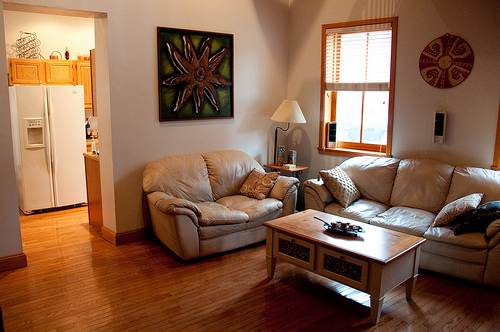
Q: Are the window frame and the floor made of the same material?
A: Yes, both the window frame and the floor are made of wood.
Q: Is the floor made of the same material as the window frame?
A: Yes, both the floor and the window frame are made of wood.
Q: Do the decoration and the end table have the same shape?
A: No, the decoration is round and the end table is square.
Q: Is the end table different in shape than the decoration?
A: Yes, the decoration is round and the end table is square.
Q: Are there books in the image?
A: No, there are no books.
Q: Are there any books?
A: No, there are no books.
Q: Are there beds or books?
A: No, there are no books or beds.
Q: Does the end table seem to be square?
A: Yes, the end table is square.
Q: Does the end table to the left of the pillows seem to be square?
A: Yes, the end table is square.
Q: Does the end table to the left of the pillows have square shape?
A: Yes, the end table is square.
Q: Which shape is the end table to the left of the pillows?
A: The end table is square.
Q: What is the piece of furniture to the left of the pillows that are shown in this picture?
A: The piece of furniture is an end table.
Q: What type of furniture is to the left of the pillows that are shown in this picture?
A: The piece of furniture is an end table.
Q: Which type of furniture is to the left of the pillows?
A: The piece of furniture is an end table.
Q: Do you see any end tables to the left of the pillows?
A: Yes, there is an end table to the left of the pillows.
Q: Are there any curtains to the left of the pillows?
A: No, there is an end table to the left of the pillows.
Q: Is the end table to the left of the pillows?
A: Yes, the end table is to the left of the pillows.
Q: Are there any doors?
A: Yes, there is a door.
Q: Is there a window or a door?
A: Yes, there is a door.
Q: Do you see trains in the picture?
A: No, there are no trains.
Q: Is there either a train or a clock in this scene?
A: No, there are no trains or clocks.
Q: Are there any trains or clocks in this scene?
A: No, there are no trains or clocks.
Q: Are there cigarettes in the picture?
A: No, there are no cigarettes.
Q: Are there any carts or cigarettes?
A: No, there are no cigarettes or carts.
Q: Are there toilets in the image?
A: No, there are no toilets.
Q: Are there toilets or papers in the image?
A: No, there are no toilets or papers.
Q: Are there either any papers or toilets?
A: No, there are no toilets or papers.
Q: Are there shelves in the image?
A: No, there are no shelves.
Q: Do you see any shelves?
A: No, there are no shelves.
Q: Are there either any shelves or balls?
A: No, there are no shelves or balls.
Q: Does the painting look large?
A: Yes, the painting is large.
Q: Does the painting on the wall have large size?
A: Yes, the painting is large.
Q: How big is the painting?
A: The painting is large.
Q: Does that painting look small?
A: No, the painting is large.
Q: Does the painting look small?
A: No, the painting is large.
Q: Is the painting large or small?
A: The painting is large.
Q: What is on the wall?
A: The painting is on the wall.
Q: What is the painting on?
A: The painting is on the wall.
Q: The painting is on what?
A: The painting is on the wall.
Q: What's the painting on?
A: The painting is on the wall.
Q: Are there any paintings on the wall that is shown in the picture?
A: Yes, there is a painting on the wall.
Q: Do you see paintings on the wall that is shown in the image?
A: Yes, there is a painting on the wall.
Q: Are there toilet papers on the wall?
A: No, there is a painting on the wall.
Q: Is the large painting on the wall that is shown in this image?
A: Yes, the painting is on the wall.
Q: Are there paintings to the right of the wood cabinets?
A: Yes, there is a painting to the right of the cabinets.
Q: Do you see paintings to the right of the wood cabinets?
A: Yes, there is a painting to the right of the cabinets.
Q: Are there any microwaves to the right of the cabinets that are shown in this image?
A: No, there is a painting to the right of the cabinets.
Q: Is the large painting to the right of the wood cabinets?
A: Yes, the painting is to the right of the cabinets.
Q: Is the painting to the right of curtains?
A: No, the painting is to the right of the cabinets.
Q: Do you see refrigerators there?
A: Yes, there is a refrigerator.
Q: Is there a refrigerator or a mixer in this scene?
A: Yes, there is a refrigerator.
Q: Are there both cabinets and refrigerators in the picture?
A: Yes, there are both a refrigerator and a cabinet.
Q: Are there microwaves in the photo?
A: No, there are no microwaves.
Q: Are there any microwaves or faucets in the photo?
A: No, there are no microwaves or faucets.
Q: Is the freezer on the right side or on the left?
A: The freezer is on the left of the image.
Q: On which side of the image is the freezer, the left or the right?
A: The freezer is on the left of the image.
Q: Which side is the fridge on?
A: The fridge is on the left of the image.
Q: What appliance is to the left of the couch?
A: The appliance is a refrigerator.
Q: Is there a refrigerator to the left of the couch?
A: Yes, there is a refrigerator to the left of the couch.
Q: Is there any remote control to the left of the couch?
A: No, there is a refrigerator to the left of the couch.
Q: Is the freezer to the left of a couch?
A: Yes, the freezer is to the left of a couch.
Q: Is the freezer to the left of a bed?
A: No, the freezer is to the left of a couch.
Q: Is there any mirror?
A: No, there are no mirrors.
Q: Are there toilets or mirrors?
A: No, there are no mirrors or toilets.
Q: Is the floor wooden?
A: Yes, the floor is wooden.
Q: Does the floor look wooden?
A: Yes, the floor is wooden.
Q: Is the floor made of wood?
A: Yes, the floor is made of wood.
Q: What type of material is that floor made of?
A: The floor is made of wood.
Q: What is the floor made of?
A: The floor is made of wood.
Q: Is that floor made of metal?
A: No, the floor is made of wood.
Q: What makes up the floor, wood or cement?
A: The floor is made of wood.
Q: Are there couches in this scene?
A: Yes, there is a couch.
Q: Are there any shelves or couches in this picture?
A: Yes, there is a couch.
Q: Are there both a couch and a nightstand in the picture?
A: No, there is a couch but no nightstands.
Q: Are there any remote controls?
A: No, there are no remote controls.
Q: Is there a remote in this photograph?
A: No, there are no remote controls.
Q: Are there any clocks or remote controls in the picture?
A: No, there are no remote controls or clocks.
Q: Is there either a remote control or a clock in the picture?
A: No, there are no remote controls or clocks.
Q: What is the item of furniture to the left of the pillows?
A: The piece of furniture is a couch.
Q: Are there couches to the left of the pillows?
A: Yes, there is a couch to the left of the pillows.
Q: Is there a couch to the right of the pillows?
A: No, the couch is to the left of the pillows.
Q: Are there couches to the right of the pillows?
A: No, the couch is to the left of the pillows.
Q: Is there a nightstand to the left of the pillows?
A: No, there is a couch to the left of the pillows.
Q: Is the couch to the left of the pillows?
A: Yes, the couch is to the left of the pillows.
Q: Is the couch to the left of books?
A: No, the couch is to the left of the pillows.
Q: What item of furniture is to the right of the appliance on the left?
A: The piece of furniture is a couch.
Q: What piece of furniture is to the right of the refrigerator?
A: The piece of furniture is a couch.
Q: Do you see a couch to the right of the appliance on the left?
A: Yes, there is a couch to the right of the refrigerator.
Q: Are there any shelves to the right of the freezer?
A: No, there is a couch to the right of the freezer.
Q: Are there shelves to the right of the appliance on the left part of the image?
A: No, there is a couch to the right of the freezer.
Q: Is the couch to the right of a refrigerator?
A: Yes, the couch is to the right of a refrigerator.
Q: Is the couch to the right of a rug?
A: No, the couch is to the right of a refrigerator.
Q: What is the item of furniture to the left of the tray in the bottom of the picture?
A: The piece of furniture is a couch.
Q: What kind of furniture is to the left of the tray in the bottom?
A: The piece of furniture is a couch.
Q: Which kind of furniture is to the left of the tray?
A: The piece of furniture is a couch.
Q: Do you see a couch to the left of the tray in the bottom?
A: Yes, there is a couch to the left of the tray.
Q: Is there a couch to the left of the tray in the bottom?
A: Yes, there is a couch to the left of the tray.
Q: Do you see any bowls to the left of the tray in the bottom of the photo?
A: No, there is a couch to the left of the tray.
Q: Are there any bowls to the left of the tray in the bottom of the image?
A: No, there is a couch to the left of the tray.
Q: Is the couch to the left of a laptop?
A: No, the couch is to the left of the tray.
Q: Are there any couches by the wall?
A: Yes, there is a couch by the wall.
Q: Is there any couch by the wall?
A: Yes, there is a couch by the wall.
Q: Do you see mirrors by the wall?
A: No, there is a couch by the wall.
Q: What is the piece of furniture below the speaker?
A: The piece of furniture is a couch.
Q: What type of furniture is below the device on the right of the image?
A: The piece of furniture is a couch.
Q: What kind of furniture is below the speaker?
A: The piece of furniture is a couch.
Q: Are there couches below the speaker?
A: Yes, there is a couch below the speaker.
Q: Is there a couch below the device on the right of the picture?
A: Yes, there is a couch below the speaker.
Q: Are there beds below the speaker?
A: No, there is a couch below the speaker.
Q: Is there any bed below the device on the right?
A: No, there is a couch below the speaker.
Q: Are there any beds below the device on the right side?
A: No, there is a couch below the speaker.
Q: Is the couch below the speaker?
A: Yes, the couch is below the speaker.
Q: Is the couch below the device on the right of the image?
A: Yes, the couch is below the speaker.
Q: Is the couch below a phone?
A: No, the couch is below the speaker.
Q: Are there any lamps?
A: Yes, there is a lamp.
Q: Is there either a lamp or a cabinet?
A: Yes, there is a lamp.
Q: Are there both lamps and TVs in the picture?
A: No, there is a lamp but no televisions.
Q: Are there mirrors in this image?
A: No, there are no mirrors.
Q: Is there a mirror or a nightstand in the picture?
A: No, there are no mirrors or nightstands.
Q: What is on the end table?
A: The lamp is on the end table.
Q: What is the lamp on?
A: The lamp is on the end table.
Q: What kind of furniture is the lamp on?
A: The lamp is on the end table.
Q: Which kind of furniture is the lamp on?
A: The lamp is on the end table.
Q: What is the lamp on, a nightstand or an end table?
A: The lamp is on an end table.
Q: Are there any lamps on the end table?
A: Yes, there is a lamp on the end table.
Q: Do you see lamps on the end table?
A: Yes, there is a lamp on the end table.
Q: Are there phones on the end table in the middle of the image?
A: No, there is a lamp on the end table.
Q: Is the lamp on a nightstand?
A: No, the lamp is on an end table.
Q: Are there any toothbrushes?
A: No, there are no toothbrushes.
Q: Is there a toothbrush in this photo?
A: No, there are no toothbrushes.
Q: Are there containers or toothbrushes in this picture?
A: No, there are no toothbrushes or containers.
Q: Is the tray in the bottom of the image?
A: Yes, the tray is in the bottom of the image.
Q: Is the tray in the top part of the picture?
A: No, the tray is in the bottom of the image.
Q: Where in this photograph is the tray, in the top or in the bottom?
A: The tray is in the bottom of the image.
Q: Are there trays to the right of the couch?
A: Yes, there is a tray to the right of the couch.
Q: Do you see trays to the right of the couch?
A: Yes, there is a tray to the right of the couch.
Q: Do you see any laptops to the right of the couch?
A: No, there is a tray to the right of the couch.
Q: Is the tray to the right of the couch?
A: Yes, the tray is to the right of the couch.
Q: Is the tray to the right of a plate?
A: No, the tray is to the right of the couch.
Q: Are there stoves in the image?
A: No, there are no stoves.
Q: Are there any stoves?
A: No, there are no stoves.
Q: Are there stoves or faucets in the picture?
A: No, there are no stoves or faucets.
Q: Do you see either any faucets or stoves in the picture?
A: No, there are no stoves or faucets.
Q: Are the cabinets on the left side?
A: Yes, the cabinets are on the left of the image.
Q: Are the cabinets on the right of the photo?
A: No, the cabinets are on the left of the image.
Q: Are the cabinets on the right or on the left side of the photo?
A: The cabinets are on the left of the image.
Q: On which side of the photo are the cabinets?
A: The cabinets are on the left of the image.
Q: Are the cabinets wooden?
A: Yes, the cabinets are wooden.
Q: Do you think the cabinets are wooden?
A: Yes, the cabinets are wooden.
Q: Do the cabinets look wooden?
A: Yes, the cabinets are wooden.